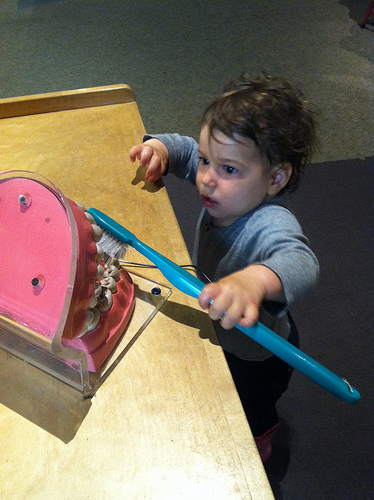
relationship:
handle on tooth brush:
[150, 256, 361, 403] [83, 206, 360, 402]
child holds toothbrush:
[119, 77, 322, 347] [73, 204, 251, 286]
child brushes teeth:
[119, 77, 322, 347] [196, 192, 213, 202]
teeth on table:
[0, 167, 139, 374] [1, 81, 277, 498]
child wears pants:
[119, 77, 322, 347] [224, 311, 299, 436]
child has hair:
[119, 77, 322, 347] [199, 62, 324, 200]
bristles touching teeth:
[97, 232, 130, 260] [63, 189, 131, 352]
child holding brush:
[119, 94, 310, 346] [86, 199, 363, 425]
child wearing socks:
[119, 77, 322, 347] [253, 425, 276, 473]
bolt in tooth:
[30, 275, 39, 287] [89, 221, 101, 242]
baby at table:
[122, 74, 349, 473] [20, 72, 313, 480]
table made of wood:
[1, 83, 194, 284] [9, 119, 123, 165]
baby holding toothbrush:
[128, 74, 321, 479] [98, 203, 369, 409]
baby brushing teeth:
[128, 74, 321, 479] [0, 167, 139, 374]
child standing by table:
[119, 77, 322, 347] [1, 81, 277, 498]